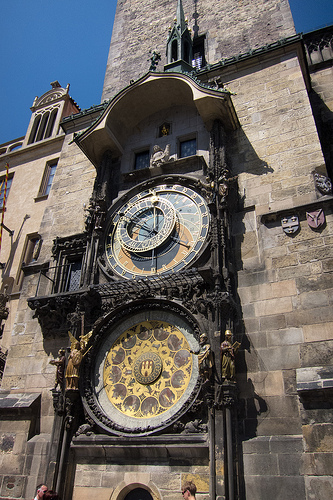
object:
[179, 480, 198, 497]
head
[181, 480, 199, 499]
person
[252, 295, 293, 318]
brick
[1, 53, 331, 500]
wall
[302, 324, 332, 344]
brick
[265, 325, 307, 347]
brick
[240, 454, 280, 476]
brick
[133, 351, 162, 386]
centerpiece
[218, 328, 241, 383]
man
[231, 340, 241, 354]
something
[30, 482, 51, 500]
man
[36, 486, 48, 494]
glasses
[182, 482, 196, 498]
top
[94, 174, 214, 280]
clock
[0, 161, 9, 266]
pole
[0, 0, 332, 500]
building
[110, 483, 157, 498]
opening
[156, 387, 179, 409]
symbol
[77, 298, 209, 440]
circle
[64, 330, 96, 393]
statue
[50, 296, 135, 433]
left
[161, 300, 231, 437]
right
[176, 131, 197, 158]
window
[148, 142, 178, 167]
statue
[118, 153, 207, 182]
top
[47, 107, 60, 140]
window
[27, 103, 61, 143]
row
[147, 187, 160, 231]
hand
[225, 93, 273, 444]
shadow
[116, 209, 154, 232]
hand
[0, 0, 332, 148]
sky